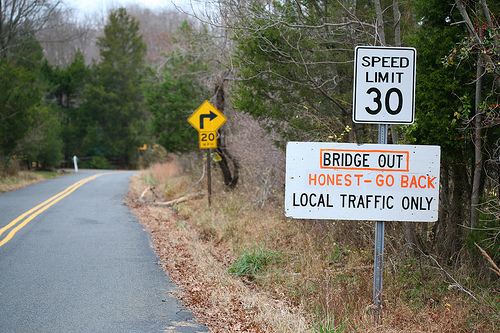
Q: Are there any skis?
A: No, there are no skis.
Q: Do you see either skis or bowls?
A: No, there are no skis or bowls.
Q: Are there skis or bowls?
A: No, there are no skis or bowls.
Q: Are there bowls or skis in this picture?
A: No, there are no skis or bowls.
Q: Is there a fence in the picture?
A: No, there are no fences.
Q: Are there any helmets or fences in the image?
A: No, there are no fences or helmets.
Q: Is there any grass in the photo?
A: Yes, there is grass.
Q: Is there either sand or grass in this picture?
A: Yes, there is grass.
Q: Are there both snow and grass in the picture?
A: No, there is grass but no snow.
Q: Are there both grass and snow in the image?
A: No, there is grass but no snow.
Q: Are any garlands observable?
A: No, there are no garlands.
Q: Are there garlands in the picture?
A: No, there are no garlands.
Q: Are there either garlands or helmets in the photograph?
A: No, there are no garlands or helmets.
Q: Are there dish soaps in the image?
A: No, there are no dish soaps.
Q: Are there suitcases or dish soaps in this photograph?
A: No, there are no dish soaps or suitcases.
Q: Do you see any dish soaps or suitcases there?
A: No, there are no dish soaps or suitcases.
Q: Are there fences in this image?
A: No, there are no fences.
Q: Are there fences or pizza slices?
A: No, there are no fences or pizza slices.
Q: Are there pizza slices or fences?
A: No, there are no fences or pizza slices.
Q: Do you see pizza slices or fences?
A: No, there are no fences or pizza slices.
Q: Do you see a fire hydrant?
A: No, there are no fire hydrants.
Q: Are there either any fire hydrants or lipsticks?
A: No, there are no fire hydrants or lipsticks.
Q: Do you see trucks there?
A: No, there are no trucks.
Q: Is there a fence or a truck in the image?
A: No, there are no trucks or fences.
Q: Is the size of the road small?
A: Yes, the road is small.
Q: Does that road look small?
A: Yes, the road is small.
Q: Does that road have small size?
A: Yes, the road is small.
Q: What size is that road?
A: The road is small.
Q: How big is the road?
A: The road is small.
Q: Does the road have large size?
A: No, the road is small.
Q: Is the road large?
A: No, the road is small.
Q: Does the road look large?
A: No, the road is small.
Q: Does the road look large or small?
A: The road is small.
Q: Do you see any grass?
A: Yes, there is grass.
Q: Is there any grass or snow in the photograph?
A: Yes, there is grass.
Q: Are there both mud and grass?
A: No, there is grass but no mud.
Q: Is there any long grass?
A: Yes, there is long grass.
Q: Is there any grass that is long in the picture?
A: Yes, there is long grass.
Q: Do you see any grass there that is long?
A: Yes, there is grass that is long.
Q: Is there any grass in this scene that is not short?
A: Yes, there is long grass.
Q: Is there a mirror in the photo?
A: No, there are no mirrors.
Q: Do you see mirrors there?
A: No, there are no mirrors.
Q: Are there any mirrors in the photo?
A: No, there are no mirrors.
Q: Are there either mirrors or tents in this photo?
A: No, there are no mirrors or tents.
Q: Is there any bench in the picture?
A: No, there are no benches.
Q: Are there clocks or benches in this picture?
A: No, there are no benches or clocks.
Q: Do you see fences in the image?
A: No, there are no fences.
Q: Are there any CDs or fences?
A: No, there are no fences or cds.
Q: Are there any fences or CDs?
A: No, there are no fences or cds.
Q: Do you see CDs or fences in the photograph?
A: No, there are no fences or cds.